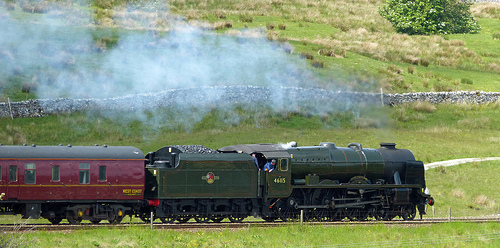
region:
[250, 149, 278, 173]
two train conductors riding in green train car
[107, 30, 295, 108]
white smoke coming from the train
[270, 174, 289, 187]
yellow numbers on the side of the train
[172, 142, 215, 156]
pile of black coal in the train car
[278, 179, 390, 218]
large wheels on the first train car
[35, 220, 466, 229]
train tracks under the train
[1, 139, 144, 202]
third train car is red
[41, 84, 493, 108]
stone wall in the brackground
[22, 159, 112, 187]
windows on the side of the train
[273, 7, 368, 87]
grass on the other side of brick wall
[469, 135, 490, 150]
patch of green grass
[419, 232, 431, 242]
patch of green grass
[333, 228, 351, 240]
patch of green grass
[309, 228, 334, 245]
patch of green grass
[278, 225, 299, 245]
patch of green grass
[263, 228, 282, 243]
patch of green grass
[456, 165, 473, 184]
patch of green grass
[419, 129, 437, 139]
patch of green grass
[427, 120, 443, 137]
patch of green grass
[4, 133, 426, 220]
the train on the tracks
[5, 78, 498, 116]
the wall on the hillside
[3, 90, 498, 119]
the wall is stone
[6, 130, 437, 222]
the train is old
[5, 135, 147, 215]
the red car of the train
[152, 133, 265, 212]
the coal on the train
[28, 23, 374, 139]
smoking coming out of the train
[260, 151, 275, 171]
the engineer on the train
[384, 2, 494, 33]
the large bush on the hill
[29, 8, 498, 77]
grass on the hill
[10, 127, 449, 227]
green and red train going down the tracks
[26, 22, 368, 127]
large puff of smoke coming from the engine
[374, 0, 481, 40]
large green tree in the field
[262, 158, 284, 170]
man in blue driving the train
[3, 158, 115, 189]
line of windows on the passenger car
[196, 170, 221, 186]
logo of the train company on the engine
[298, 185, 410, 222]
large wheels on the front of the engine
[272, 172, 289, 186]
yellow id number on the engine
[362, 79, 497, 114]
stone wall in the field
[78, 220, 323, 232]
brown train track under the train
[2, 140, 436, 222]
a train chugging down the track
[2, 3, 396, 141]
train smoke from the stack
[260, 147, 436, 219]
green train engine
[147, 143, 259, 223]
a green coal car behind the engine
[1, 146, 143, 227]
a red passenger car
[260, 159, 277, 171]
the train engineer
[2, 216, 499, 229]
the train track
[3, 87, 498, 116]
a gray stacked stone wall on the hill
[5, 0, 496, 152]
the grassy hill behind the train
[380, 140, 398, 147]
short smoke stack on the train engine